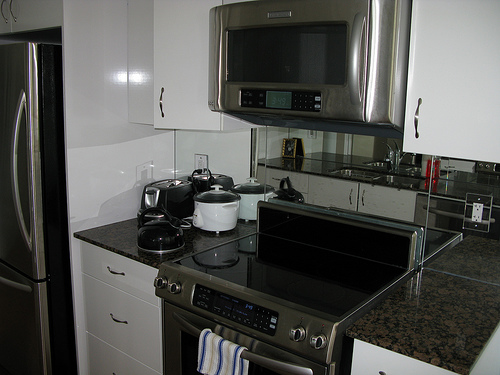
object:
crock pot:
[195, 183, 239, 233]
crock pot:
[235, 177, 272, 220]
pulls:
[102, 263, 128, 325]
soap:
[424, 153, 441, 184]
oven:
[142, 177, 194, 217]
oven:
[161, 217, 403, 373]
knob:
[288, 328, 306, 344]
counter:
[65, 176, 291, 273]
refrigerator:
[0, 35, 70, 374]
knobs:
[151, 275, 170, 291]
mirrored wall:
[246, 127, 438, 218]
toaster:
[135, 172, 199, 227]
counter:
[353, 264, 498, 370]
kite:
[440, 247, 488, 342]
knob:
[168, 282, 183, 298]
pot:
[138, 219, 178, 247]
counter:
[76, 185, 256, 264]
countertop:
[347, 234, 495, 370]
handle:
[413, 98, 423, 139]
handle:
[106, 265, 126, 275]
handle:
[107, 313, 128, 326]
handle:
[99, 304, 129, 338]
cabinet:
[68, 196, 495, 373]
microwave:
[209, 0, 411, 137]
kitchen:
[1, 1, 498, 373]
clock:
[216, 292, 267, 341]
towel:
[190, 325, 252, 373]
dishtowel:
[186, 326, 254, 374]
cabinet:
[393, 1, 498, 169]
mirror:
[250, 120, 498, 237]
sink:
[331, 167, 381, 179]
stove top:
[167, 234, 408, 316]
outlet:
[465, 199, 487, 224]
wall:
[418, 159, 499, 254]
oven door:
[146, 258, 332, 372]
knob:
[308, 330, 329, 350]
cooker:
[183, 179, 245, 239]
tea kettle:
[134, 206, 199, 258]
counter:
[83, 218, 220, 260]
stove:
[159, 198, 392, 373]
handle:
[154, 82, 170, 123]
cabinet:
[149, 0, 256, 137]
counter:
[352, 215, 497, 372]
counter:
[73, 197, 333, 287]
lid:
[194, 182, 240, 203]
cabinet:
[66, 236, 201, 309]